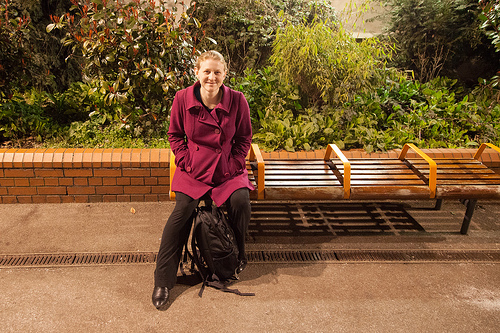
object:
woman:
[151, 49, 255, 309]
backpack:
[184, 207, 255, 300]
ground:
[3, 201, 497, 332]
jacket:
[167, 81, 256, 208]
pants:
[153, 189, 251, 289]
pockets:
[179, 157, 192, 172]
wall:
[4, 151, 498, 203]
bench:
[168, 143, 499, 234]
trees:
[2, 3, 499, 155]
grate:
[252, 249, 331, 263]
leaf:
[130, 207, 135, 214]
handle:
[249, 144, 265, 200]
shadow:
[242, 198, 428, 244]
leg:
[460, 199, 477, 234]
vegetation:
[4, 88, 497, 149]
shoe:
[152, 286, 170, 309]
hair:
[196, 50, 227, 72]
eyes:
[215, 71, 221, 74]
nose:
[208, 72, 217, 80]